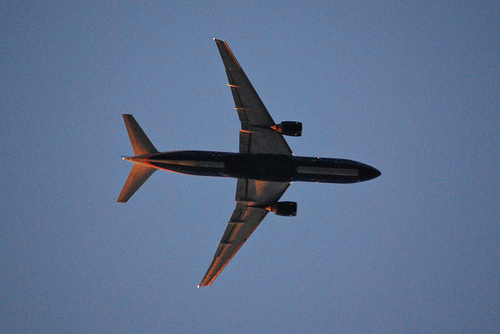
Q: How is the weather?
A: It is cloudless.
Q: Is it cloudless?
A: Yes, it is cloudless.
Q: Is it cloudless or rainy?
A: It is cloudless.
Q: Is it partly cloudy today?
A: No, it is cloudless.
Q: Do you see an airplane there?
A: Yes, there is an airplane.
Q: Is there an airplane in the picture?
A: Yes, there is an airplane.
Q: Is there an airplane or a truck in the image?
A: Yes, there is an airplane.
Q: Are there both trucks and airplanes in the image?
A: No, there is an airplane but no trucks.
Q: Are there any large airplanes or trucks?
A: Yes, there is a large airplane.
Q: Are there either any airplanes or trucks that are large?
A: Yes, the airplane is large.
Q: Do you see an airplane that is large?
A: Yes, there is a large airplane.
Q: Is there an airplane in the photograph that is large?
A: Yes, there is an airplane that is large.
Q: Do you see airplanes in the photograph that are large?
A: Yes, there is an airplane that is large.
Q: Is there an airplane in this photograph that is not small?
A: Yes, there is a large airplane.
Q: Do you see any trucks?
A: No, there are no trucks.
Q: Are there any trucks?
A: No, there are no trucks.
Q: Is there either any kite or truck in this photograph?
A: No, there are no trucks or kites.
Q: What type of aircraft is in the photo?
A: The aircraft is an airplane.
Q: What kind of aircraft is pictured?
A: The aircraft is an airplane.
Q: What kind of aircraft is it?
A: The aircraft is an airplane.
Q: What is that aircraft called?
A: This is an airplane.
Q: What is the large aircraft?
A: The aircraft is an airplane.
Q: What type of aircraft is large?
A: The aircraft is an airplane.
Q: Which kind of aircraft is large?
A: The aircraft is an airplane.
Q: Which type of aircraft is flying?
A: The aircraft is an airplane.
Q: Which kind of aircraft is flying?
A: The aircraft is an airplane.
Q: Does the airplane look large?
A: Yes, the airplane is large.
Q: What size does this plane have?
A: The plane has large size.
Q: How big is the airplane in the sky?
A: The plane is large.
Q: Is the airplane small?
A: No, the airplane is large.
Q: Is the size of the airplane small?
A: No, the airplane is large.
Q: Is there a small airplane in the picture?
A: No, there is an airplane but it is large.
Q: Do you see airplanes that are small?
A: No, there is an airplane but it is large.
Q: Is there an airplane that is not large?
A: No, there is an airplane but it is large.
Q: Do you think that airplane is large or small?
A: The airplane is large.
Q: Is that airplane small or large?
A: The airplane is large.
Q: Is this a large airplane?
A: Yes, this is a large airplane.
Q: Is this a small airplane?
A: No, this is a large airplane.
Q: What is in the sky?
A: The plane is in the sky.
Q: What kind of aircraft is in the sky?
A: The aircraft is an airplane.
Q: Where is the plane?
A: The plane is in the sky.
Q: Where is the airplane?
A: The plane is in the sky.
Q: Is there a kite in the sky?
A: No, there is an airplane in the sky.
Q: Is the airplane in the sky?
A: Yes, the airplane is in the sky.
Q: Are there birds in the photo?
A: No, there are no birds.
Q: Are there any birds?
A: No, there are no birds.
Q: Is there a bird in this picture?
A: No, there are no birds.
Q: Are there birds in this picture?
A: No, there are no birds.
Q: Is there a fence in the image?
A: No, there are no fences.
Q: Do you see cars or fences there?
A: No, there are no fences or cars.